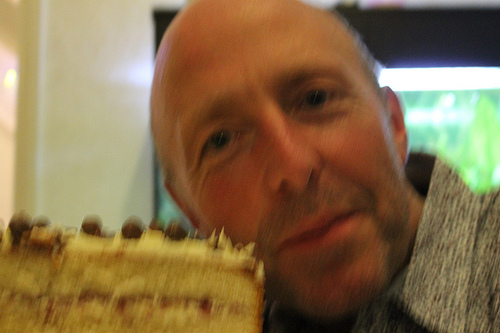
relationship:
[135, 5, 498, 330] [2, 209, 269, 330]
man by cake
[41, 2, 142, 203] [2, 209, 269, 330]
wall behind cake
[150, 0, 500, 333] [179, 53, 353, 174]
man has crows feet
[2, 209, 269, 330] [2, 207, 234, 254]
cake has topping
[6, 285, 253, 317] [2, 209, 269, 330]
filling inside cake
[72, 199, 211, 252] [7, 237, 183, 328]
balls on cake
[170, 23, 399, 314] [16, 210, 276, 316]
face beside cake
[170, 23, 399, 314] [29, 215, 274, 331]
face beside cake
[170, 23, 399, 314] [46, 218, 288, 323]
face beside cake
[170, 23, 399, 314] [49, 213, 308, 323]
face beside cake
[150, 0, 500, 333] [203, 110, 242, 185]
man has eye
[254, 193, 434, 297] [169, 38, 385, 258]
hair on mans face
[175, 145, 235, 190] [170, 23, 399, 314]
wrinkle on side of face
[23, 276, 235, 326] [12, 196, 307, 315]
chocolate frosting in cake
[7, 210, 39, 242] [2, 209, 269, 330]
walnut on top of cake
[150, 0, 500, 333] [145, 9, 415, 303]
man has head